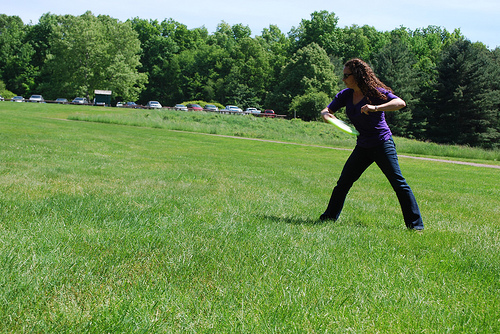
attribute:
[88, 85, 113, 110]
shed — green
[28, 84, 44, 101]
car — parked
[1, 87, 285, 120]
cars — parked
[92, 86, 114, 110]
rest room — park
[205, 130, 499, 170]
path — dirt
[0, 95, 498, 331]
field — grassy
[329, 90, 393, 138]
shirt — purple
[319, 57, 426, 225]
woman — denim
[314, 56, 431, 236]
girl — playing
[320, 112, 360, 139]
frisbee — white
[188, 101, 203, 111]
car — parked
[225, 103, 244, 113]
car — parked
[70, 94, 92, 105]
car — parked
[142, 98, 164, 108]
car — parked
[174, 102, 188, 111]
car — parked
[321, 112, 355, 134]
frisbee — game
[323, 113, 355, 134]
frisbee — yellow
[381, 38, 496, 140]
pine trees — green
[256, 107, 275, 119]
cars — parked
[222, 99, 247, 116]
cars — parked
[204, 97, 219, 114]
cars — parked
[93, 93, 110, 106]
cars — parked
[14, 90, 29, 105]
cars — parked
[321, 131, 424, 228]
pants — blue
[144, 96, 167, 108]
car — white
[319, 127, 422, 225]
jeans — blue